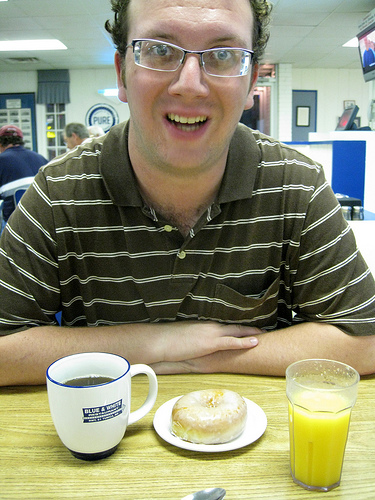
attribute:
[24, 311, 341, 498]
table — wood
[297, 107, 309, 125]
sign — white, rectangular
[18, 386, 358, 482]
wooden table — brown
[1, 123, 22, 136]
hat — red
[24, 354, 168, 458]
mug — white and blue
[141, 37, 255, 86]
eyeglasses — thin framed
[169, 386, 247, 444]
donut — in foreground, glazed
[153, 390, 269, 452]
plate — small, white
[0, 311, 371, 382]
arms — folded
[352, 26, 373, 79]
television — on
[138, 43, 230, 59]
eyes — blue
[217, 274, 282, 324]
pocket — white, tee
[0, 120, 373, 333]
shirt — green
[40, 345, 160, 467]
cup — white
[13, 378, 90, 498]
table — wooden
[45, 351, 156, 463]
mug — white, coffee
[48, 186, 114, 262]
stripes — white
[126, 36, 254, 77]
glasses — pair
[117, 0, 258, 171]
face — man's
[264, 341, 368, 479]
glass — full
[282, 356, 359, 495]
glass — in foreground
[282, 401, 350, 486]
juice — orange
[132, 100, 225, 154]
mouth — smiling